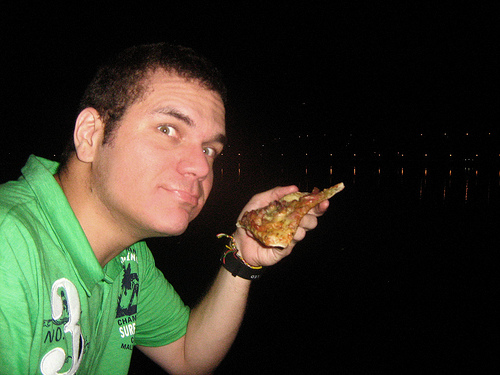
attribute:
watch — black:
[218, 245, 267, 282]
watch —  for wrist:
[216, 246, 266, 283]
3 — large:
[37, 274, 84, 374]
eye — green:
[154, 123, 186, 143]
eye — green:
[201, 134, 219, 161]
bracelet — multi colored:
[176, 219, 301, 314]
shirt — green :
[11, 233, 148, 368]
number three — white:
[38, 277, 84, 374]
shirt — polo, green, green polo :
[2, 156, 199, 373]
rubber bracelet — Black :
[214, 237, 261, 290]